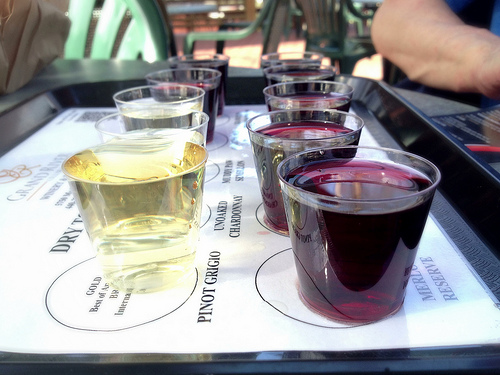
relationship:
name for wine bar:
[8, 148, 78, 207] [2, 1, 499, 371]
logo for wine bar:
[0, 157, 46, 184] [2, 1, 499, 371]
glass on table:
[276, 146, 440, 324] [13, 54, 498, 361]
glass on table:
[259, 49, 349, 80] [2, 37, 489, 373]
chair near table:
[184, 2, 284, 66] [159, 5, 218, 15]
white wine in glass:
[63, 136, 205, 294] [58, 133, 215, 297]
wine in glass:
[298, 159, 450, 341] [276, 146, 440, 324]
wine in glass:
[252, 121, 362, 231] [237, 106, 370, 242]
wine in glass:
[266, 93, 352, 125] [263, 77, 356, 126]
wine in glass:
[266, 93, 352, 125] [264, 60, 339, 109]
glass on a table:
[60, 139, 207, 299] [60, 62, 365, 88]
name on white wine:
[194, 249, 222, 321] [63, 136, 205, 294]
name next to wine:
[405, 252, 462, 304] [278, 157, 442, 328]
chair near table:
[36, 0, 178, 63] [20, 47, 464, 114]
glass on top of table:
[237, 106, 370, 242] [13, 54, 498, 361]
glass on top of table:
[223, 106, 448, 327] [0, 68, 492, 370]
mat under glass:
[0, 98, 493, 351] [276, 146, 440, 324]